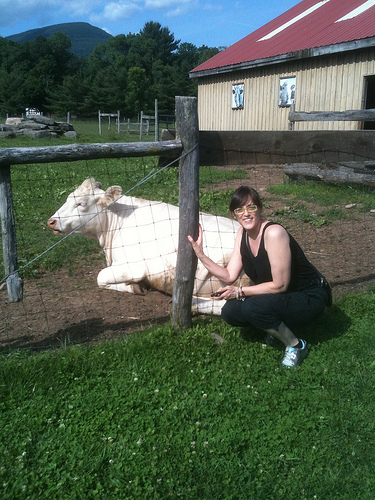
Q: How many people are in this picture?
A: 1.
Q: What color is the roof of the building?
A: Red.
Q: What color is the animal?
A: White.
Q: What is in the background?
A: Trees and Mountains.